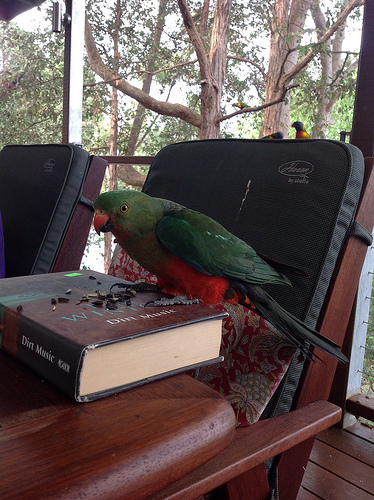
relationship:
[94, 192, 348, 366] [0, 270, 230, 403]
bird sitting on a book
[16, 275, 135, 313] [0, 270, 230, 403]
food on a book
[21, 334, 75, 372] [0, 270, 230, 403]
writing on side of book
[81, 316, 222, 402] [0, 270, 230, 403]
pages of a book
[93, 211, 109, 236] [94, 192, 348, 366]
beak on a bird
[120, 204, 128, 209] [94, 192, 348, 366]
eye of a bird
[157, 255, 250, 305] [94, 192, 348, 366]
bottom of a bird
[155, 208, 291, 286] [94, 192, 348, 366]
wing of a bird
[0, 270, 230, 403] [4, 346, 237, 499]
book on a table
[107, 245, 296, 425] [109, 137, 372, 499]
cushion on a chair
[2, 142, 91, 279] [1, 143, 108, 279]
cushion on a chair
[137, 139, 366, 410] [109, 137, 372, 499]
cushion on a chair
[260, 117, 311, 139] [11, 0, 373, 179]
birds in background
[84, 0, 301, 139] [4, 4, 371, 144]
tree in background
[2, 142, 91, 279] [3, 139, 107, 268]
cushion on chair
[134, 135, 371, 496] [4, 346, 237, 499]
chair at table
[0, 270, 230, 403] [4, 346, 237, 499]
book on table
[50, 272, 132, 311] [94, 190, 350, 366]
food for bird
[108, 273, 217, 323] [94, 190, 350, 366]
claws of bird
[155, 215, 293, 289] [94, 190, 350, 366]
wing of bird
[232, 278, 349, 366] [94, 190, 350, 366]
feathers of bird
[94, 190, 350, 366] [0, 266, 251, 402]
bird sitting on book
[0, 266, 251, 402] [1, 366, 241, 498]
book sitting on wood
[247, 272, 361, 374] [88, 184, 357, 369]
feathers of bird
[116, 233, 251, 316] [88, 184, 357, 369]
underneath of bird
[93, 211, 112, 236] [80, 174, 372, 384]
beak of bird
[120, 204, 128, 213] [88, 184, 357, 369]
eye of bird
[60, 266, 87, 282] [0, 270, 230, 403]
sticker on book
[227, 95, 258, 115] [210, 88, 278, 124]
bird on branch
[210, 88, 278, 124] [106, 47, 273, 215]
branch of tree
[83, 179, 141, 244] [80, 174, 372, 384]
head of bird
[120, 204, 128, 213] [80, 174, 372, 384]
eye of bird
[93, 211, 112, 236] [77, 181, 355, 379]
beak of bird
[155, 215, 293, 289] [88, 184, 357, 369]
wing of bird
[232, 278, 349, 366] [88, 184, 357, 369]
feathers of bird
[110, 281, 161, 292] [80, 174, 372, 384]
claws of bird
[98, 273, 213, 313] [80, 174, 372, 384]
leg of bird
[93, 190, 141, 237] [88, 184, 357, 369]
head of bird